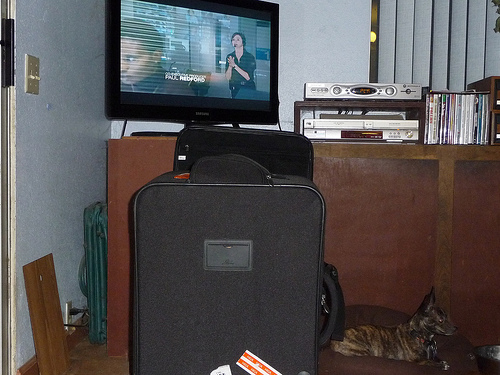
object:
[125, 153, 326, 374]
luggage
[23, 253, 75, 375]
wood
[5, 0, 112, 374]
wall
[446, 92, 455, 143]
movie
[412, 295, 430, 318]
ear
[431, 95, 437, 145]
dvd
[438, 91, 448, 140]
dvd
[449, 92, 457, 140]
dvd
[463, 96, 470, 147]
dvd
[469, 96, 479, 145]
dvd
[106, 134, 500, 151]
counter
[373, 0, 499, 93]
blinds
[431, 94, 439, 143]
movie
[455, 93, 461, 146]
movie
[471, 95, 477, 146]
movie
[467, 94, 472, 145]
movie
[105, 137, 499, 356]
desk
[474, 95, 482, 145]
movie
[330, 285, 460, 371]
dog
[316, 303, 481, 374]
bed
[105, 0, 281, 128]
tv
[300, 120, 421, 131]
player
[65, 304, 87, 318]
plug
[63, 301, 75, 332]
outlet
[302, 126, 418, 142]
dvd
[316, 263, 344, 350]
handle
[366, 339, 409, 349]
fur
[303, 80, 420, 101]
box